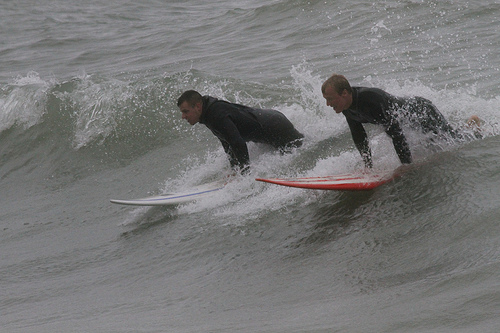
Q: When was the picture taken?
A: Daytime.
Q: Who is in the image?
A: Two surfers.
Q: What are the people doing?
A: Surfing.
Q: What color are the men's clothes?
A: Black.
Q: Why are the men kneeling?
A: They are surfing.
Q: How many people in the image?
A: Two.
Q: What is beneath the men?
A: Surfboards.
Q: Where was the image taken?
A: The beach.